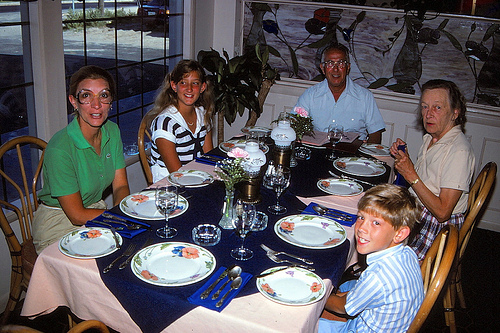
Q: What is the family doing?
A: Waiting on dinner.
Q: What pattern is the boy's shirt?
A: Striped.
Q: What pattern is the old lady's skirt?
A: Plaid.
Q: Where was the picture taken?
A: Dining room.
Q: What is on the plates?
A: Flowers.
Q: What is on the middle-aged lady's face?
A: Glasses.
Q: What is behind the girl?
A: Window.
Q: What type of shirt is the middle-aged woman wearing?
A: Polo.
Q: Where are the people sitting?
A: Around a table.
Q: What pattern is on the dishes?
A: Floral.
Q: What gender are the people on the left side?
A: Female.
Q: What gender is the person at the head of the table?
A: Male.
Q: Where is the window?
A: Behind the 2 women on the left.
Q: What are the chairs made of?
A: Wood.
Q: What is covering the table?
A: Tablecloth.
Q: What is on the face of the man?
A: Glasses.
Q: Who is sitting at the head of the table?
A: Man in blue shirt.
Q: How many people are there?
A: 5.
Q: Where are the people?
A: Dining room.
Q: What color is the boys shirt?
A: White and blue.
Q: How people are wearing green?
A: One.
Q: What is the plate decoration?
A: Flowers.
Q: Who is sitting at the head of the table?
A: The man.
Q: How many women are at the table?
A: 3.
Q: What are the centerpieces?
A: Flowers.